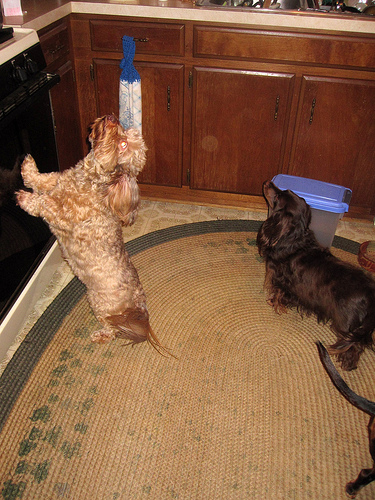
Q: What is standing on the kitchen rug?
A: Dogs.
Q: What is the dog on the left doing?
A: Jumping on black stove.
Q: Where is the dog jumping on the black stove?
A: In kitchen.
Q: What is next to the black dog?
A: Blue and clear tupperware container.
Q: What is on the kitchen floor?
A: Blue and clear tupperware container.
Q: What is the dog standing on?
A: A rug.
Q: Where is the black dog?
A: Standing on a rug.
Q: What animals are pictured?
A: Dogs.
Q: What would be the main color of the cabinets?
A: Brown.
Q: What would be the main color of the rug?
A: Brown.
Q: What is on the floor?
A: Rug.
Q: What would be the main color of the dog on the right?
A: Brown.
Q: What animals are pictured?
A: Dogs.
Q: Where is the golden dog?
A: Jumping on the oven door.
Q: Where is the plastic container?
A: Behind the brown dog.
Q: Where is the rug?
A: On the floor.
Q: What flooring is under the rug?
A: Linoleum.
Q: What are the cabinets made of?
A: Wood.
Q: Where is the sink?
A: Above the cabinets.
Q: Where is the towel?
A: Hanging from the cabinet handle.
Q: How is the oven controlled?
A: The knobs above the oven door.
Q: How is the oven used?
A: To cook food.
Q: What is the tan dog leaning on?
A: Stove.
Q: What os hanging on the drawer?
A: Towel.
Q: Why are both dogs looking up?
A: They see food.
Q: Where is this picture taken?
A: Kitchen.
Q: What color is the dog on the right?
A: Brown.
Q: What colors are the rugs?
A: Brown and green.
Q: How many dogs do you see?
A: Two.